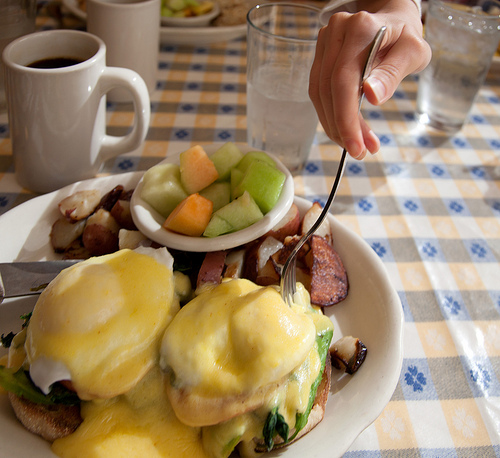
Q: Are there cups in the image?
A: Yes, there is a cup.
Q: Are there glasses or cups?
A: Yes, there is a cup.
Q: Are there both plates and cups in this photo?
A: Yes, there are both a cup and a plate.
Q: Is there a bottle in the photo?
A: No, there are no bottles.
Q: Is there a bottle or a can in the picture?
A: No, there are no bottles or cans.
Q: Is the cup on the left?
A: Yes, the cup is on the left of the image.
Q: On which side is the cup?
A: The cup is on the left of the image.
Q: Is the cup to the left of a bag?
A: No, the cup is to the left of a melon.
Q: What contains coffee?
A: The cup contains coffee.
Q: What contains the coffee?
A: The cup contains coffee.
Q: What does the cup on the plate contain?
A: The cup contains coffee.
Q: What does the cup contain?
A: The cup contains coffee.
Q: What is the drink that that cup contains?
A: The drink is coffee.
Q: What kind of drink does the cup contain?
A: The cup contains coffee.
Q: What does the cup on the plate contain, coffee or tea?
A: The cup contains coffee.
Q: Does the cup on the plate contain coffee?
A: Yes, the cup contains coffee.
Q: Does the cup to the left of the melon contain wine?
A: No, the cup contains coffee.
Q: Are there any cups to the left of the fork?
A: Yes, there is a cup to the left of the fork.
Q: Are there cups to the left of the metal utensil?
A: Yes, there is a cup to the left of the fork.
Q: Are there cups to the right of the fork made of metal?
A: No, the cup is to the left of the fork.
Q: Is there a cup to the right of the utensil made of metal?
A: No, the cup is to the left of the fork.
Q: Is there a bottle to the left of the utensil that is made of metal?
A: No, there is a cup to the left of the fork.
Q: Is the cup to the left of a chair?
A: No, the cup is to the left of the fork.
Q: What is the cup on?
A: The cup is on the plate.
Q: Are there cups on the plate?
A: Yes, there is a cup on the plate.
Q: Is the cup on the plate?
A: Yes, the cup is on the plate.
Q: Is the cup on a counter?
A: No, the cup is on the plate.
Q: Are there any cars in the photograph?
A: No, there are no cars.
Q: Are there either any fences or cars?
A: No, there are no cars or fences.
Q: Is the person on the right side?
A: Yes, the person is on the right of the image.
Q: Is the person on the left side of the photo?
A: No, the person is on the right of the image.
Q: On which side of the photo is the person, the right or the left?
A: The person is on the right of the image.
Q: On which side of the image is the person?
A: The person is on the right of the image.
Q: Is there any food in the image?
A: Yes, there is food.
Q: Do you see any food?
A: Yes, there is food.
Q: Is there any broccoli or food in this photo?
A: Yes, there is food.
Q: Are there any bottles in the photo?
A: No, there are no bottles.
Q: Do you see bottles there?
A: No, there are no bottles.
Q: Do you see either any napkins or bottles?
A: No, there are no bottles or napkins.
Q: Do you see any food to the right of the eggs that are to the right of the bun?
A: Yes, there is food to the right of the eggs.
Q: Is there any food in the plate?
A: Yes, there is food in the plate.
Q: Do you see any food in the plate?
A: Yes, there is food in the plate.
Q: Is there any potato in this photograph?
A: Yes, there are potatoes.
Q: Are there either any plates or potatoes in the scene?
A: Yes, there are potatoes.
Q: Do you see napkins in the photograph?
A: No, there are no napkins.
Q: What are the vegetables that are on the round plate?
A: The vegetables are potatoes.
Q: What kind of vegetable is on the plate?
A: The vegetables are potatoes.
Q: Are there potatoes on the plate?
A: Yes, there are potatoes on the plate.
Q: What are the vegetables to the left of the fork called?
A: The vegetables are potatoes.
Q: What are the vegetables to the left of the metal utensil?
A: The vegetables are potatoes.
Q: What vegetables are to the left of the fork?
A: The vegetables are potatoes.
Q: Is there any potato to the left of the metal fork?
A: Yes, there are potatoes to the left of the fork.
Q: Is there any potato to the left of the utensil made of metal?
A: Yes, there are potatoes to the left of the fork.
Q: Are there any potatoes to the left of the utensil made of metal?
A: Yes, there are potatoes to the left of the fork.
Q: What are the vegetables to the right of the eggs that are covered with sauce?
A: The vegetables are potatoes.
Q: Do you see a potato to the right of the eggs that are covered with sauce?
A: Yes, there are potatoes to the right of the eggs.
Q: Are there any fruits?
A: Yes, there is a fruit.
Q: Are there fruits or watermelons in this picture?
A: Yes, there is a fruit.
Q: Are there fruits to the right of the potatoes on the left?
A: Yes, there is a fruit to the right of the potatoes.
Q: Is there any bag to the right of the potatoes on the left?
A: No, there is a fruit to the right of the potatoes.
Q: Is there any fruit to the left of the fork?
A: Yes, there is a fruit to the left of the fork.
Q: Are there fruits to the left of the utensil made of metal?
A: Yes, there is a fruit to the left of the fork.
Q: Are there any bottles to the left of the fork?
A: No, there is a fruit to the left of the fork.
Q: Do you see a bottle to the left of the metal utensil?
A: No, there is a fruit to the left of the fork.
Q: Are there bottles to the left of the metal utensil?
A: No, there is a fruit to the left of the fork.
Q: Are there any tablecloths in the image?
A: Yes, there is a tablecloth.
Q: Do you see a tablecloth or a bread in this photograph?
A: Yes, there is a tablecloth.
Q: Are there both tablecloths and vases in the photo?
A: No, there is a tablecloth but no vases.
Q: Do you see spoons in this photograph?
A: No, there are no spoons.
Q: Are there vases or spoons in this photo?
A: No, there are no spoons or vases.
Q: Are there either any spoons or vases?
A: No, there are no spoons or vases.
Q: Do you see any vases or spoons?
A: No, there are no spoons or vases.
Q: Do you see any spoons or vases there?
A: No, there are no spoons or vases.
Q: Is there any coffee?
A: Yes, there is coffee.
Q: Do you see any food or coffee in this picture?
A: Yes, there is coffee.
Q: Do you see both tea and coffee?
A: No, there is coffee but no tea.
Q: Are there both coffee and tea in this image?
A: No, there is coffee but no tea.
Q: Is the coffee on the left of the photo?
A: Yes, the coffee is on the left of the image.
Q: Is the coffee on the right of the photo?
A: No, the coffee is on the left of the image.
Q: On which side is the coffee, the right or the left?
A: The coffee is on the left of the image.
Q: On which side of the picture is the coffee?
A: The coffee is on the left of the image.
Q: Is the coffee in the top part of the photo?
A: Yes, the coffee is in the top of the image.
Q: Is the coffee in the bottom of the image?
A: No, the coffee is in the top of the image.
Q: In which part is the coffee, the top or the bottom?
A: The coffee is in the top of the image.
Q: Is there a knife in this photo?
A: Yes, there is a knife.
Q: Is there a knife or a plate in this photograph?
A: Yes, there is a knife.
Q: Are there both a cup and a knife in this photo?
A: Yes, there are both a knife and a cup.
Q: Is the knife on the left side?
A: Yes, the knife is on the left of the image.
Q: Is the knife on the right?
A: No, the knife is on the left of the image.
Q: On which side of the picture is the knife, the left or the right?
A: The knife is on the left of the image.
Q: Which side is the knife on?
A: The knife is on the left of the image.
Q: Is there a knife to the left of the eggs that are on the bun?
A: Yes, there is a knife to the left of the eggs.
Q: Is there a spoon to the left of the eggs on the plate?
A: No, there is a knife to the left of the eggs.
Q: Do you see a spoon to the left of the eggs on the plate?
A: No, there is a knife to the left of the eggs.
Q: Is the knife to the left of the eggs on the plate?
A: Yes, the knife is to the left of the eggs.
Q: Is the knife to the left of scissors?
A: No, the knife is to the left of the eggs.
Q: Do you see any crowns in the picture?
A: No, there are no crowns.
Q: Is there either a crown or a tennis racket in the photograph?
A: No, there are no crowns or rackets.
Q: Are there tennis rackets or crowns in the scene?
A: No, there are no crowns or tennis rackets.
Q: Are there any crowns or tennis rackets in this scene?
A: No, there are no crowns or tennis rackets.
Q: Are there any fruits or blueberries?
A: Yes, there is a fruit.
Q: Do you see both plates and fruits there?
A: Yes, there are both a fruit and a plate.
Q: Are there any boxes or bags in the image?
A: No, there are no boxes or bags.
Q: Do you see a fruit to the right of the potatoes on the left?
A: Yes, there is a fruit to the right of the potatoes.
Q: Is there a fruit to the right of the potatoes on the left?
A: Yes, there is a fruit to the right of the potatoes.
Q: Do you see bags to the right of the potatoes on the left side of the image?
A: No, there is a fruit to the right of the potatoes.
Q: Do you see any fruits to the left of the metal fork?
A: Yes, there is a fruit to the left of the fork.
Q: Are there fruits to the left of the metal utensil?
A: Yes, there is a fruit to the left of the fork.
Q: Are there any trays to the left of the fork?
A: No, there is a fruit to the left of the fork.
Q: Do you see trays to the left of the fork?
A: No, there is a fruit to the left of the fork.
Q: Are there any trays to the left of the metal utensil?
A: No, there is a fruit to the left of the fork.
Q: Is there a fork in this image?
A: Yes, there is a fork.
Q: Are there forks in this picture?
A: Yes, there is a fork.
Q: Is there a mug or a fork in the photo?
A: Yes, there is a fork.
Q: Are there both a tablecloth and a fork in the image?
A: Yes, there are both a fork and a tablecloth.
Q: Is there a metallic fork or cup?
A: Yes, there is a metal fork.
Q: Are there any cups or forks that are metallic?
A: Yes, the fork is metallic.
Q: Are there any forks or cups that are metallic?
A: Yes, the fork is metallic.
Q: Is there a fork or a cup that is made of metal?
A: Yes, the fork is made of metal.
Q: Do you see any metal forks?
A: Yes, there is a metal fork.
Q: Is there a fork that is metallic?
A: Yes, there is a fork that is metallic.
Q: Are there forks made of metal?
A: Yes, there is a fork that is made of metal.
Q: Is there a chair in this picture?
A: No, there are no chairs.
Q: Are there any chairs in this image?
A: No, there are no chairs.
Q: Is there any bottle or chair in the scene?
A: No, there are no chairs or bottles.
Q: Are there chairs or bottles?
A: No, there are no chairs or bottles.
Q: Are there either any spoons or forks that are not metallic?
A: No, there is a fork but it is metallic.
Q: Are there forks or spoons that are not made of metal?
A: No, there is a fork but it is made of metal.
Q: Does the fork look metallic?
A: Yes, the fork is metallic.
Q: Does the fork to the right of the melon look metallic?
A: Yes, the fork is metallic.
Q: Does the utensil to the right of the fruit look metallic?
A: Yes, the fork is metallic.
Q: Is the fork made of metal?
A: Yes, the fork is made of metal.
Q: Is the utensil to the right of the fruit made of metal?
A: Yes, the fork is made of metal.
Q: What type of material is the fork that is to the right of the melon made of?
A: The fork is made of metal.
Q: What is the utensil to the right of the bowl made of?
A: The fork is made of metal.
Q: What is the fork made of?
A: The fork is made of metal.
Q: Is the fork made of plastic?
A: No, the fork is made of metal.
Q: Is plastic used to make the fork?
A: No, the fork is made of metal.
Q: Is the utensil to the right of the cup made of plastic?
A: No, the fork is made of metal.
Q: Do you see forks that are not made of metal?
A: No, there is a fork but it is made of metal.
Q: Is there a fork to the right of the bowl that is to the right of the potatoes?
A: Yes, there is a fork to the right of the bowl.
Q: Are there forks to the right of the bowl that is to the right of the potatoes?
A: Yes, there is a fork to the right of the bowl.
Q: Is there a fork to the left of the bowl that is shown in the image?
A: No, the fork is to the right of the bowl.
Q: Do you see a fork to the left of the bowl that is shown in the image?
A: No, the fork is to the right of the bowl.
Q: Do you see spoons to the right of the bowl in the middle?
A: No, there is a fork to the right of the bowl.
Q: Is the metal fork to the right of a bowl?
A: Yes, the fork is to the right of a bowl.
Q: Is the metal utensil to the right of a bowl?
A: Yes, the fork is to the right of a bowl.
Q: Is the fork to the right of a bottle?
A: No, the fork is to the right of a bowl.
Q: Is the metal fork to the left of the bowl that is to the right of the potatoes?
A: No, the fork is to the right of the bowl.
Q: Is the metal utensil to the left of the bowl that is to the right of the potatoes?
A: No, the fork is to the right of the bowl.